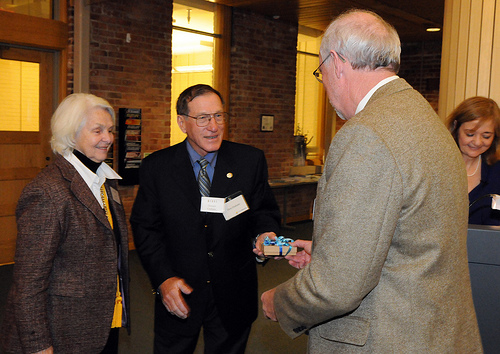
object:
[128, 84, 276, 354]
person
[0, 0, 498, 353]
gathering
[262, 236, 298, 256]
gift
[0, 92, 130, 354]
woman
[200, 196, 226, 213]
tag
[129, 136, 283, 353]
suit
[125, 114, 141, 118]
pamphlet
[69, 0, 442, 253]
wall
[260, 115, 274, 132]
plaque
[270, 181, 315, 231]
table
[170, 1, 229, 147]
window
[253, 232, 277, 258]
hand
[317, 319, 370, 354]
pocket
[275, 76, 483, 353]
jacket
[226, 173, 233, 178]
button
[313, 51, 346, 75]
glasses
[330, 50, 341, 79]
ear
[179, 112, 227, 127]
glasses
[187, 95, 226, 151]
face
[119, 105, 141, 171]
magazine holder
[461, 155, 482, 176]
necklace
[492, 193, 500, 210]
tag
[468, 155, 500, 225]
shirt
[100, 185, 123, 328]
tassels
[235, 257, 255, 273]
pocket cover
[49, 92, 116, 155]
hair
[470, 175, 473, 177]
pearl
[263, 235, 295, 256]
ribbon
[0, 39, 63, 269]
door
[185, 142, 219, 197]
shirt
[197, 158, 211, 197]
tie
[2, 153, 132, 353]
jacket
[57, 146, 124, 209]
shirt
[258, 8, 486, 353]
man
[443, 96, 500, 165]
hair